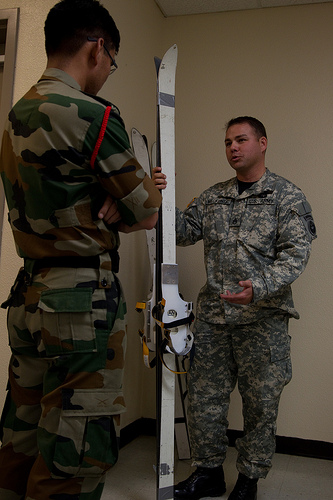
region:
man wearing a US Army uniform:
[163, 104, 314, 498]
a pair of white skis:
[139, 37, 205, 497]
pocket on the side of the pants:
[57, 388, 135, 476]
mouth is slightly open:
[228, 154, 245, 163]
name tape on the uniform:
[199, 197, 237, 208]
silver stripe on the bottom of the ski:
[155, 483, 177, 499]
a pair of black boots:
[170, 454, 270, 498]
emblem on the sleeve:
[306, 216, 321, 238]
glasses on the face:
[80, 38, 125, 77]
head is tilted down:
[39, 0, 130, 109]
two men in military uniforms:
[2, 2, 317, 496]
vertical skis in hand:
[141, 43, 191, 498]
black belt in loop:
[21, 251, 121, 284]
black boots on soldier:
[173, 464, 257, 498]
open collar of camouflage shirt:
[166, 169, 313, 322]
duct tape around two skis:
[155, 91, 175, 108]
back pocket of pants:
[39, 288, 98, 356]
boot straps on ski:
[152, 293, 194, 374]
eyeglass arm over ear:
[88, 36, 118, 75]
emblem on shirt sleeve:
[295, 211, 318, 241]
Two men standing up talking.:
[202, 454, 263, 488]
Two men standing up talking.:
[125, 312, 152, 332]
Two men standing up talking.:
[206, 245, 224, 329]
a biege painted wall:
[192, 13, 331, 93]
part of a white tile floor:
[279, 457, 327, 498]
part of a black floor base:
[276, 434, 331, 457]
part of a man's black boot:
[224, 470, 266, 499]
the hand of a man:
[215, 280, 252, 304]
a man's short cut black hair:
[224, 115, 272, 155]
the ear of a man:
[90, 37, 106, 68]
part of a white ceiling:
[163, 0, 270, 11]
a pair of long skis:
[137, 41, 196, 499]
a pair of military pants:
[188, 308, 291, 482]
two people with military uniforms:
[1, 3, 326, 496]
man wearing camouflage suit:
[172, 104, 315, 491]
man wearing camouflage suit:
[0, 0, 160, 494]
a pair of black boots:
[166, 462, 262, 499]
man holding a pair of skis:
[145, 33, 319, 499]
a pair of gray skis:
[148, 37, 204, 498]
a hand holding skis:
[150, 160, 179, 201]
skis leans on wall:
[128, 124, 195, 465]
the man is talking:
[183, 105, 323, 263]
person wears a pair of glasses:
[0, 3, 167, 198]